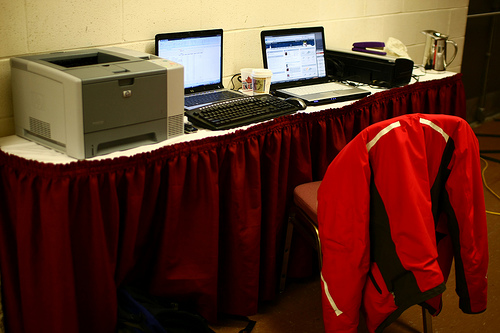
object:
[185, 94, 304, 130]
keyboard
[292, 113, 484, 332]
chair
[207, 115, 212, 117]
black key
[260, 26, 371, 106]
computer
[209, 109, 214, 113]
key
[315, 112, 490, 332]
jacket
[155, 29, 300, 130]
computer